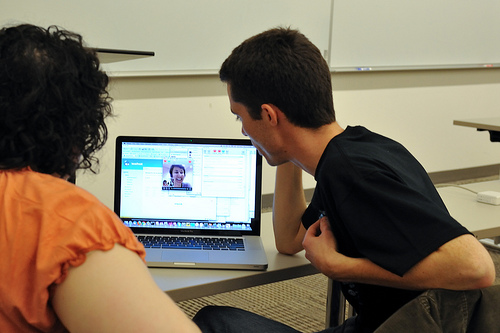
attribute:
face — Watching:
[163, 161, 194, 187]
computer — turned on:
[118, 133, 283, 279]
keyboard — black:
[134, 229, 265, 274]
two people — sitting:
[1, 12, 406, 315]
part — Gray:
[447, 169, 499, 255]